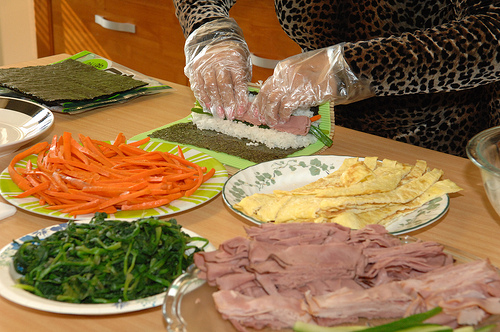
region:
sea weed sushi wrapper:
[7, 46, 144, 116]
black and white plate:
[5, 85, 57, 150]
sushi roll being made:
[122, 46, 347, 146]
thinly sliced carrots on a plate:
[7, 131, 233, 218]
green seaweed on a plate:
[18, 212, 183, 308]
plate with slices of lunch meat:
[185, 223, 478, 329]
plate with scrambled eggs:
[227, 150, 457, 226]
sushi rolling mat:
[182, 71, 362, 144]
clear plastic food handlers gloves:
[168, 26, 256, 117]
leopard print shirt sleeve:
[343, 28, 492, 110]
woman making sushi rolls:
[147, 1, 499, 171]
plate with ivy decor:
[221, 153, 451, 235]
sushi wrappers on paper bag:
[1, 49, 176, 118]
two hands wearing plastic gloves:
[181, 28, 357, 128]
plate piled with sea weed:
[1, 210, 219, 314]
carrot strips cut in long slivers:
[7, 128, 213, 216]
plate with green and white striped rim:
[1, 138, 231, 220]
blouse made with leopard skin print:
[173, 1, 498, 157]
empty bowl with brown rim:
[0, 95, 54, 157]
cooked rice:
[188, 93, 320, 150]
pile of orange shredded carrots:
[21, 134, 196, 206]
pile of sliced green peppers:
[16, 211, 176, 291]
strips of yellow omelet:
[259, 167, 422, 217]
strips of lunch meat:
[208, 223, 498, 328]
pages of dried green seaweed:
[3, 52, 145, 118]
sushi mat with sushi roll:
[141, 81, 360, 181]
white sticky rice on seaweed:
[191, 110, 300, 156]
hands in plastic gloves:
[172, 16, 396, 138]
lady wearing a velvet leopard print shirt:
[338, 12, 490, 109]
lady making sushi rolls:
[128, 40, 346, 174]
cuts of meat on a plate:
[190, 220, 498, 330]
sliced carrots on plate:
[6, 130, 216, 215]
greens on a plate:
[9, 211, 211, 304]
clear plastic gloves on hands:
[182, 16, 364, 123]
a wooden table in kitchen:
[90, 116, 149, 128]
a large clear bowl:
[464, 121, 499, 214]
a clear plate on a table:
[160, 259, 236, 330]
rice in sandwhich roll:
[188, 93, 318, 150]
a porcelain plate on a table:
[0, 96, 55, 148]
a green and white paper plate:
[162, 200, 190, 212]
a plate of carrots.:
[12, 139, 218, 215]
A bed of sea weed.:
[1, 62, 155, 104]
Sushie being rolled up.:
[176, 73, 313, 147]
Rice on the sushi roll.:
[193, 116, 298, 148]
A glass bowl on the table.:
[464, 125, 498, 218]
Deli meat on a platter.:
[206, 228, 491, 322]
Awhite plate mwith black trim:
[0, 83, 60, 153]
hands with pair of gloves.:
[180, 15, 359, 122]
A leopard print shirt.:
[269, 1, 499, 158]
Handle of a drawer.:
[94, 6, 145, 36]